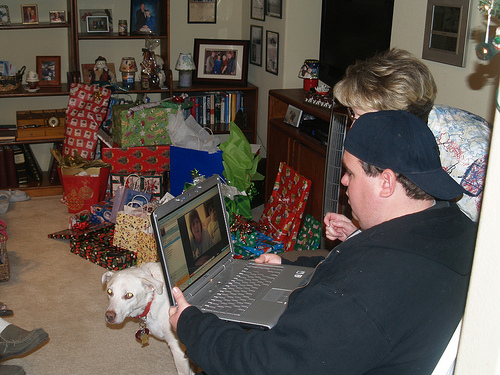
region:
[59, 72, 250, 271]
Christmas presents in a pile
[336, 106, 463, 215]
backwards cap on man's head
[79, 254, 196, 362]
white dog with red collar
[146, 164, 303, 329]
open laptop on man's lap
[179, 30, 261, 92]
framed photo on shelf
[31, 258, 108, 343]
carpeted floor in livingroom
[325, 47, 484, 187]
blonde woman looking at laptop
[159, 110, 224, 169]
tissue paper in gift bag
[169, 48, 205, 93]
small lamp on shelf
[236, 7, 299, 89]
framed pictures on wall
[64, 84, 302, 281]
There are lots of Christmas presents on the floor.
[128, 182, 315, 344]
The man is holding a laptop.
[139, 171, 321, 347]
The laptop is on.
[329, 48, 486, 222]
A woman is looking over the man's shoulder.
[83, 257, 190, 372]
There is a white dog staring into the camera.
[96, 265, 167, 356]
The dog is wearing a red collar.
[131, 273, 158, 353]
The dog's tags are on the collar.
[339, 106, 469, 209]
The man is wearing a baseball cap.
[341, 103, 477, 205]
The baseball cap is on backwards.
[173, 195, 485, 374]
The man is wearing a sweatshirt.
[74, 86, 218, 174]
Pile of wrapped gifts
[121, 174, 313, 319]
open lap top computer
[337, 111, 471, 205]
Man with backwards cap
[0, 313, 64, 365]
Single foot in shoe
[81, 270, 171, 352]
White dog face with beedy eyes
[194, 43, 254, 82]
family picture on shelf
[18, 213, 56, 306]
Beige carpet on floor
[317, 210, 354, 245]
Woman's hand beside man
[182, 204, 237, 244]
Video chatting with a girl on computer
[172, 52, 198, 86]
Candle lamp on shelf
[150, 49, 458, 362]
man in navy outfit and woman looking at a laptop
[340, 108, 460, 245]
man wearing nay blue baseball cap backwards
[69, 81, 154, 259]
presents are stacked up for Christmas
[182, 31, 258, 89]
framed family picture on table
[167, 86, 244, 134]
books on a shelf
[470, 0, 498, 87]
Christmas tree decorations and lights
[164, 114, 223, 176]
present in a shopping bag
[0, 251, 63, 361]
grey man's slipper or casual shoe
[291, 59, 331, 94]
snowman Christmas decoration on table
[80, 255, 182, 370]
white dog with red collar and id tags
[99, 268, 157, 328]
White dog.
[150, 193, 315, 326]
Laptop computer.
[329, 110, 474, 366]
Man with a blue baseball cap.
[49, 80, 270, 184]
Christmas presents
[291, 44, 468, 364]
Two people sitting on a couch.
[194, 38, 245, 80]
Family picture in a frame.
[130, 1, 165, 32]
Wedding photo in a frame.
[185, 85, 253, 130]
Books on a shelf.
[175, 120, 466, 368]
Person holding a laptop computer.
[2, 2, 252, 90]
Shelving unit with decorations.